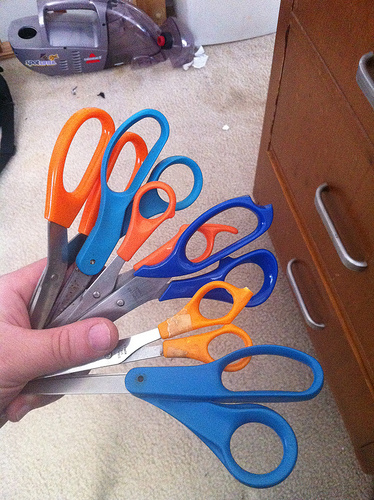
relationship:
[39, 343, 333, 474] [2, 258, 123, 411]
scissors in hand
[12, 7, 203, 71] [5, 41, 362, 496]
carpet shampooer on floor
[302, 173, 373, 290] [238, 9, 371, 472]
handle on dresser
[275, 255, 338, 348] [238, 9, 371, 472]
handle on dresser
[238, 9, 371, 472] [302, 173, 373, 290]
dresser has handle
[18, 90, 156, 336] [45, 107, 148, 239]
scissors have handle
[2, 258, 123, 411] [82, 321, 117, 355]
hand has thumbnail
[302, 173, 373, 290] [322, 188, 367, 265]
handle has reflection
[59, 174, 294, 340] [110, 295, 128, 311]
scissors have bolt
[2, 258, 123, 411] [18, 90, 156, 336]
hand holding scissors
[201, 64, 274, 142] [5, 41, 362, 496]
stain on floor